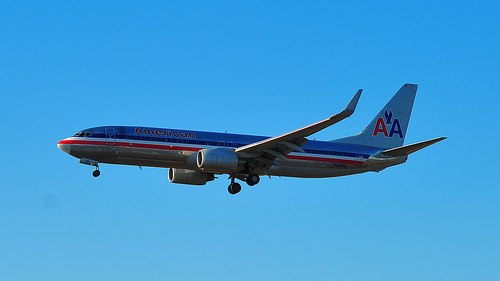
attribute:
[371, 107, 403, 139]
logo — red, white, blue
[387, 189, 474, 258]
sky — blue, clear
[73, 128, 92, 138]
windows — tinted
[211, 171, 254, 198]
wheels — several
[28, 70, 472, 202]
plane — metal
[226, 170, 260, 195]
landing gear — metal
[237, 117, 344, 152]
wing — metal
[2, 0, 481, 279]
sky — blue